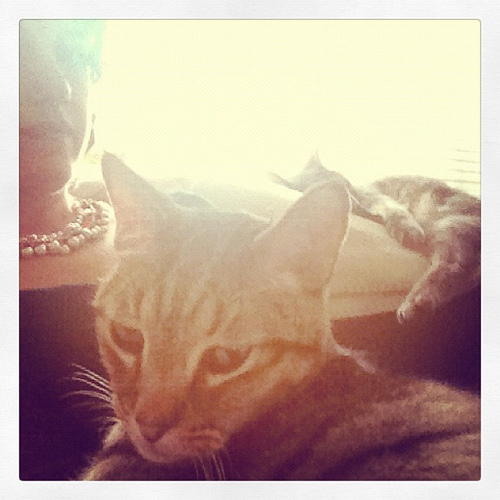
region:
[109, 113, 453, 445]
two cats in a faded picture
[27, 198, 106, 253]
pearl necklaces around a woman's neck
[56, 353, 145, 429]
whiskers of a cat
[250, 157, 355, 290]
an ear of a cat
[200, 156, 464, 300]
a pile of pillows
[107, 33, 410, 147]
sunlight coming through a window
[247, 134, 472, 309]
a cat lounging in on pillows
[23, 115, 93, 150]
a woman wearing lipstick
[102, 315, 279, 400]
the eyes of a cat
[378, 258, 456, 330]
a cat's paw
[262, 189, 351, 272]
an ear on cat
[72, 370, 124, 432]
some whiskers on cat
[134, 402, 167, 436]
nose on the cat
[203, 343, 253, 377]
an eye on the cat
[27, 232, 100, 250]
part of woman's necklace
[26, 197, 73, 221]
part of woman's neck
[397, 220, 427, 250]
one of the cat's paws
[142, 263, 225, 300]
forehead on the cat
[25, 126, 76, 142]
the mouth on woman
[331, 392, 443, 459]
striped area on cat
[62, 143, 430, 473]
gray and white striped cat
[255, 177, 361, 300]
ear of a cat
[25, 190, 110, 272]
pearl necklace around a neck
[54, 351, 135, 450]
whiskers on a cat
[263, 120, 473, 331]
cat laying on the table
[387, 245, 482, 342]
cat leg hanging off the table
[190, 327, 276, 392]
staring cat eye with fur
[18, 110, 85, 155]
lips of a lady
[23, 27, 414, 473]
lady holding a cat on her lap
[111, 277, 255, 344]
forehead creases on a cat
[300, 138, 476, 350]
the cat is sleeping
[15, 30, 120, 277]
the woman is wearing pearls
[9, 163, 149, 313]
woman wearing a necklace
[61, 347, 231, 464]
the cat has whiskers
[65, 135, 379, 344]
the cat has ears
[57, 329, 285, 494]
the whiskers are white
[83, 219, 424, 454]
the cat is stripes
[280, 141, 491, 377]
cat on the pillow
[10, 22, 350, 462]
woman looking at the cat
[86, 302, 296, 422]
cat looking at the camera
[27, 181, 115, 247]
necklace on womans body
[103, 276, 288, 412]
two green cat eyes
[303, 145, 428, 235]
sleeping cat on furniture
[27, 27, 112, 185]
woman sitting on furniture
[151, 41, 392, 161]
sun shining through window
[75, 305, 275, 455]
multiple whiskers on cats face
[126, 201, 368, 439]
fur and stripes on cat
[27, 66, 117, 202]
lipstick on womans face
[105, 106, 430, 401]
two cats laying down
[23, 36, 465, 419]
woman with two cats